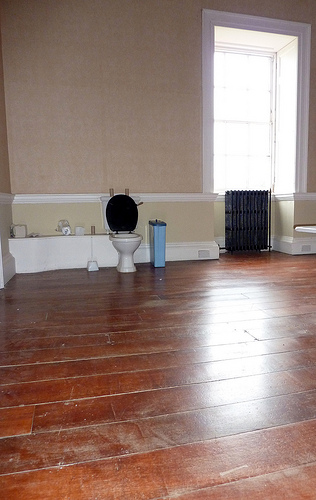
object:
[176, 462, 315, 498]
floor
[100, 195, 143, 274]
toilet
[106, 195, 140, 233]
seat cover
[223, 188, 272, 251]
radiator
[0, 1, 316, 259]
wall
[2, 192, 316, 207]
molding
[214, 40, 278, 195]
window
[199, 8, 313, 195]
frame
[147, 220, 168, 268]
trash can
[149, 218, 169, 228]
lid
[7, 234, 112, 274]
shelf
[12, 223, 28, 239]
item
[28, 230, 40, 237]
item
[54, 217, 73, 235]
item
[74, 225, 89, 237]
item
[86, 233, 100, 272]
toilet cleaner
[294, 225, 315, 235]
bath tub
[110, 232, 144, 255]
bowl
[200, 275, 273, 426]
reflection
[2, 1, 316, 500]
room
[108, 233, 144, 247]
seat